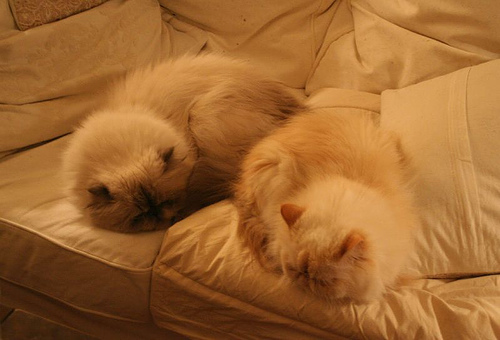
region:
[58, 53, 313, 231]
a white cat sleeping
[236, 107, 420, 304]
a white cat sleeping on a couch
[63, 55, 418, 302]
two furry white cats on a couch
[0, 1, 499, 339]
white couch with two cats on them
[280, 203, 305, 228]
a cat's right ear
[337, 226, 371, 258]
a cat's left ear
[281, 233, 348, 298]
a cat's face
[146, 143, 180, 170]
the other cat's left ear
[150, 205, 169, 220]
a cat's nose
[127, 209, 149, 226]
a cat's right eye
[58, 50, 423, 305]
two fuzzy kittens sleeping on the sofa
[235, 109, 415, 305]
tan and white cat sleeping beside another cat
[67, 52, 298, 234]
white and black cat sleeping beside another cat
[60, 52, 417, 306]
kittens sleeping on white sofa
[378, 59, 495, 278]
white pillow on the side of white and tan kitten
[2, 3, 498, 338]
photo of two kitten sleeping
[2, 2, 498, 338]
kittens sleeping together on the couch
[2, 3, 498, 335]
kittens lying on the couch sleeping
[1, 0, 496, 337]
two small kittens resting on the sofa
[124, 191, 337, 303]
closed eyes on the kittens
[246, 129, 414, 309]
fluffy orange cat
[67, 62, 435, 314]
two fluffy cats sleeping on couch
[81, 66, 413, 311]
two cats on a couch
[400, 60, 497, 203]
white pillow on couch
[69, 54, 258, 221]
cat with light brown fur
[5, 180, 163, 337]
tan seat cushion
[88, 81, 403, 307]
two cats on two seat cushions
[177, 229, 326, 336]
wrinkly tan seat cushion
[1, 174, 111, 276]
smooth tan seat cushion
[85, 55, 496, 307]
cats and a pillow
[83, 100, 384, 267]
these are two cats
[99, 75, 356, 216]
the cats are sleeping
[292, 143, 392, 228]
the cat is fury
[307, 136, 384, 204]
the cat is white in color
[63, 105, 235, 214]
the cat is fat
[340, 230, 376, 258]
the ear is small in size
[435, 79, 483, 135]
this is a pillow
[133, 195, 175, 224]
the face is black in color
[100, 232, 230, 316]
the cusions are comfy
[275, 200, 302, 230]
the ear is short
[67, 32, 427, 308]
Two cats side by side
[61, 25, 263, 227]
The cat is lying down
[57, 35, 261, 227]
The cat has brown ears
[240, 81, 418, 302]
The cat is white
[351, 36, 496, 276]
A white pillow on the couch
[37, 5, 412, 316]
The cats are lying on a couch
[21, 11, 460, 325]
The couch is white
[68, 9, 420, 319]
The cats are sleeping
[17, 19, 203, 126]
A beige couch cushion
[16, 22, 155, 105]
The cushion is worn with spots